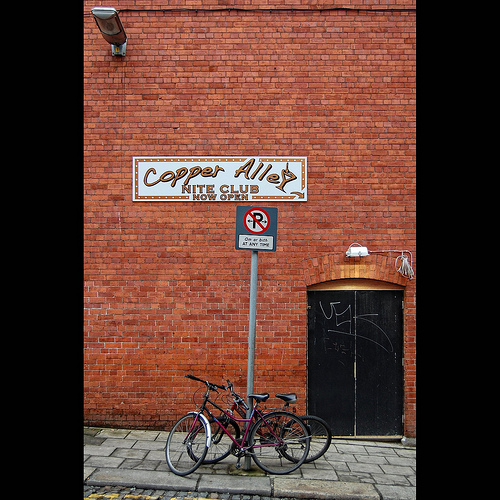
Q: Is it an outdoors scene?
A: Yes, it is outdoors.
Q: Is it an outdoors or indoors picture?
A: It is outdoors.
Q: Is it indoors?
A: No, it is outdoors.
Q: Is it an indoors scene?
A: No, it is outdoors.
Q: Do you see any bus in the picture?
A: No, there are no buses.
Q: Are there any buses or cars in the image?
A: No, there are no buses or cars.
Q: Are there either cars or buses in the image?
A: No, there are no buses or cars.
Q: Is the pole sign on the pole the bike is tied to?
A: Yes, the sign is on the pole.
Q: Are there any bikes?
A: Yes, there is a bike.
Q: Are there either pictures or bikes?
A: Yes, there is a bike.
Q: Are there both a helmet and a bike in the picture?
A: No, there is a bike but no helmets.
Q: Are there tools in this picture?
A: No, there are no tools.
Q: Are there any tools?
A: No, there are no tools.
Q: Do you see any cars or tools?
A: No, there are no tools or cars.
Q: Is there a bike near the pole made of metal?
A: Yes, there is a bike near the pole.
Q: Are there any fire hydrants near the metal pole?
A: No, there is a bike near the pole.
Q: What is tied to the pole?
A: The bike is tied to the pole.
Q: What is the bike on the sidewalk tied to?
A: The bike is tied to the pole.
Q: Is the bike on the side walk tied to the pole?
A: Yes, the bike is tied to the pole.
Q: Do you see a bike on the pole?
A: Yes, there is a bike on the pole.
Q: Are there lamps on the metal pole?
A: No, there is a bike on the pole.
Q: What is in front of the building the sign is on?
A: The bike is in front of the building.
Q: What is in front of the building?
A: The bike is in front of the building.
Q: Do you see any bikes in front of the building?
A: Yes, there is a bike in front of the building.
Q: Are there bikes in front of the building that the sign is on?
A: Yes, there is a bike in front of the building.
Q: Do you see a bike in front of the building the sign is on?
A: Yes, there is a bike in front of the building.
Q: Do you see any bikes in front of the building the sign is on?
A: Yes, there is a bike in front of the building.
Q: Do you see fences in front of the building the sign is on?
A: No, there is a bike in front of the building.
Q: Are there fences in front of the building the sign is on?
A: No, there is a bike in front of the building.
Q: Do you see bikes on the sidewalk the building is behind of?
A: Yes, there is a bike on the sidewalk.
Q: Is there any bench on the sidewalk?
A: No, there is a bike on the sidewalk.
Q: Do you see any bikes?
A: Yes, there is a bike.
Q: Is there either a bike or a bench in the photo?
A: Yes, there is a bike.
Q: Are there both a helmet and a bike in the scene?
A: No, there is a bike but no helmets.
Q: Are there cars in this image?
A: No, there are no cars.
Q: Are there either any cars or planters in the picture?
A: No, there are no cars or planters.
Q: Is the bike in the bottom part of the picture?
A: Yes, the bike is in the bottom of the image.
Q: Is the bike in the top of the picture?
A: No, the bike is in the bottom of the image.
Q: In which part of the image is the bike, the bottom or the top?
A: The bike is in the bottom of the image.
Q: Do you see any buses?
A: No, there are no buses.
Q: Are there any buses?
A: No, there are no buses.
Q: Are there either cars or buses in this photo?
A: No, there are no buses or cars.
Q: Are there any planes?
A: No, there are no planes.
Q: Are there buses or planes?
A: No, there are no planes or buses.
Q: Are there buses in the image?
A: No, there are no buses.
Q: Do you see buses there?
A: No, there are no buses.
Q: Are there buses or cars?
A: No, there are no buses or cars.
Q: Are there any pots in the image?
A: No, there are no pots.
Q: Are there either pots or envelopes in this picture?
A: No, there are no pots or envelopes.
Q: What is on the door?
A: The graffiti is on the door.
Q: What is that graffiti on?
A: The graffiti is on the door.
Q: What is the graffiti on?
A: The graffiti is on the door.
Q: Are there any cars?
A: No, there are no cars.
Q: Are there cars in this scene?
A: No, there are no cars.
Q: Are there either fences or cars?
A: No, there are no cars or fences.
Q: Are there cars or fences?
A: No, there are no cars or fences.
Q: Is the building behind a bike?
A: Yes, the building is behind a bike.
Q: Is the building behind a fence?
A: No, the building is behind a bike.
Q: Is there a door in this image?
A: Yes, there is a door.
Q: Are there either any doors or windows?
A: Yes, there is a door.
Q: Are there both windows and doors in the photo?
A: No, there is a door but no windows.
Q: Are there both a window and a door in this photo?
A: No, there is a door but no windows.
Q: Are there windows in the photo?
A: No, there are no windows.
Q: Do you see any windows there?
A: No, there are no windows.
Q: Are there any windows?
A: No, there are no windows.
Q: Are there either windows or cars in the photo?
A: No, there are no windows or cars.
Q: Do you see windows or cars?
A: No, there are no windows or cars.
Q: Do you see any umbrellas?
A: No, there are no umbrellas.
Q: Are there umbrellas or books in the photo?
A: No, there are no umbrellas or books.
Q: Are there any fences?
A: No, there are no fences.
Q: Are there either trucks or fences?
A: No, there are no fences or trucks.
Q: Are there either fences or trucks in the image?
A: No, there are no fences or trucks.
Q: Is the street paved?
A: Yes, the street is paved.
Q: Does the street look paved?
A: Yes, the street is paved.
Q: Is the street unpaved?
A: No, the street is paved.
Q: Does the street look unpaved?
A: No, the street is paved.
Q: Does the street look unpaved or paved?
A: The street is paved.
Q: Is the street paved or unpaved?
A: The street is paved.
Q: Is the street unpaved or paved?
A: The street is paved.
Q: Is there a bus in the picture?
A: No, there are no buses.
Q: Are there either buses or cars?
A: No, there are no buses or cars.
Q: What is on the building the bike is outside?
A: The sign is on the building.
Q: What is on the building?
A: The sign is on the building.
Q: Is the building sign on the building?
A: Yes, the sign is on the building.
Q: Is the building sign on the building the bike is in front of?
A: Yes, the sign is on the building.